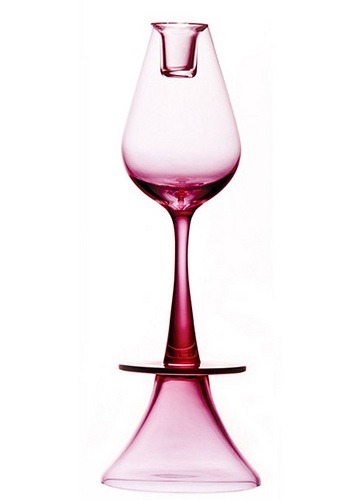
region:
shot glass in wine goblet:
[151, 19, 206, 79]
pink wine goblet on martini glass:
[109, 19, 248, 378]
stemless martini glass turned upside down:
[92, 361, 267, 495]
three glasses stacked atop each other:
[80, 14, 267, 493]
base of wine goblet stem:
[114, 352, 248, 377]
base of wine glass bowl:
[121, 160, 245, 217]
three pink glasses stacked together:
[91, 15, 265, 498]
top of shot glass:
[149, 16, 210, 31]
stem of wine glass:
[163, 207, 204, 361]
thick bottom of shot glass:
[158, 58, 200, 80]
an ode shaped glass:
[88, 1, 293, 327]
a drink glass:
[139, 31, 288, 314]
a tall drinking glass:
[95, 50, 263, 432]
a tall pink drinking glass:
[75, 37, 288, 425]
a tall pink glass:
[111, 16, 293, 416]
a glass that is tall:
[91, 8, 315, 432]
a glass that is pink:
[117, 63, 205, 475]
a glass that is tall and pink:
[97, 42, 232, 369]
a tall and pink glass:
[137, 16, 258, 420]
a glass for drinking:
[114, 54, 242, 423]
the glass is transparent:
[120, 38, 238, 470]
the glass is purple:
[130, 23, 264, 201]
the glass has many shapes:
[99, 346, 250, 490]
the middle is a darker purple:
[156, 262, 220, 373]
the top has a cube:
[150, 23, 214, 89]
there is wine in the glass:
[154, 135, 229, 230]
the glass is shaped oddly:
[106, 19, 232, 198]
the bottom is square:
[101, 446, 259, 498]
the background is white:
[83, 89, 276, 422]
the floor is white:
[95, 440, 274, 498]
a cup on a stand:
[102, 20, 260, 490]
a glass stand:
[98, 360, 264, 490]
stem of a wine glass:
[161, 209, 200, 366]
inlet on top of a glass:
[151, 20, 209, 76]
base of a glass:
[117, 360, 250, 374]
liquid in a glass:
[127, 161, 237, 211]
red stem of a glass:
[165, 210, 201, 366]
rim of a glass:
[150, 18, 209, 28]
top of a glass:
[121, 22, 241, 186]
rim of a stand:
[96, 474, 268, 494]